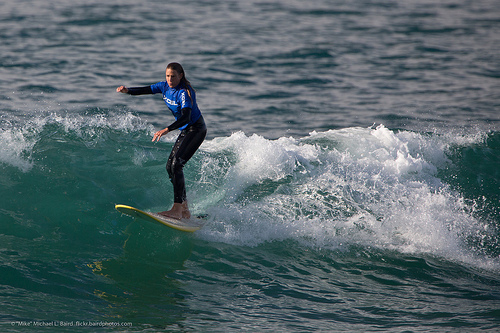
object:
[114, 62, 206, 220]
woman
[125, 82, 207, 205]
wetsuit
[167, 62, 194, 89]
hair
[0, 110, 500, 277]
wave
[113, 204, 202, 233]
surfboard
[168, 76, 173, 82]
nose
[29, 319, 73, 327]
michael bard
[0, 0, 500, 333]
photo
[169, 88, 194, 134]
arms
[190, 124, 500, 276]
wake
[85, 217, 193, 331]
shadow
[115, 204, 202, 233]
edge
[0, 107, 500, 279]
splash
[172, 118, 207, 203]
leg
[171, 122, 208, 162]
thigh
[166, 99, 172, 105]
letters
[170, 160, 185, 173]
knees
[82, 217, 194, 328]
reflection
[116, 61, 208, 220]
surfer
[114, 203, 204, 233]
board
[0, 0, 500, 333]
water